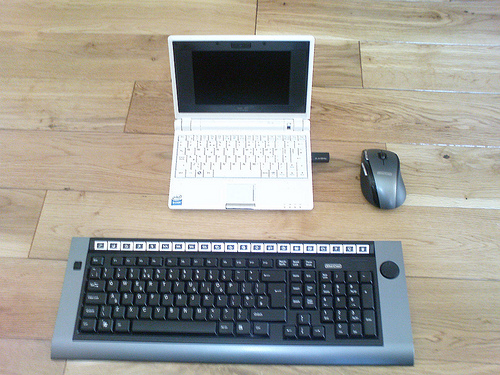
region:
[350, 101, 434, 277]
the mouse is black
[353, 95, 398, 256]
the mouse is gray and black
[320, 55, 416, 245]
the mouse is gray and black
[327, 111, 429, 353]
the mouse is gray and black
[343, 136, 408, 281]
the mouse is gray and black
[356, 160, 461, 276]
the mouse is gray and black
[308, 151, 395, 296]
the mouse is gray and black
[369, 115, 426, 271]
the mouse is gray and black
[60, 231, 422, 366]
A full keyboard in front of the laptop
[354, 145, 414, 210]
A wireless mouse next to the laptop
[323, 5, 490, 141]
Wooden surface beneath the laptop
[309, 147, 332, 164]
Wireless mouse adapter plugged into laptop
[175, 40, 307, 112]
The laptop has a small screen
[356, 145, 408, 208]
The mouse is grey and black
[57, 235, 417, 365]
The keyboard is grey and black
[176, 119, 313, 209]
The laptop is white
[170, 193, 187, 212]
A sticker on the laptop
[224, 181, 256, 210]
A white touchpad on the laptop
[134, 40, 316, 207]
white laptop with black screen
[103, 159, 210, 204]
laptop sitting on wood floor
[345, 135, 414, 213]
black mouse next to laptop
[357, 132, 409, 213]
mouse sitting on floor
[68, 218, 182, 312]
gray and black keyboard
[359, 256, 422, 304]
black circle on keyboard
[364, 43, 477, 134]
floor is wooden and brown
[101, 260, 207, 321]
keys on keyboard are black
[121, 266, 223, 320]
letters on keys are white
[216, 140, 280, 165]
letters on keys are black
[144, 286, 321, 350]
the keyboard is black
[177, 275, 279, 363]
the keyboard is black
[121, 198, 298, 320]
the keyboard is black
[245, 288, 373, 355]
the keyboard is black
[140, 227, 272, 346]
the keyboard is black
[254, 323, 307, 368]
the keyboard is black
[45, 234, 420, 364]
a wireless computer keyboard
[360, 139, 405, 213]
a black and grey computer mouse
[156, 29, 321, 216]
a white laptop computer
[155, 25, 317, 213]
an open notebook computer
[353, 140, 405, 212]
a multi button mouse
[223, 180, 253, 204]
a computer track pad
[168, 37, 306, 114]
a computer monitor screen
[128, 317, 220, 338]
a keyboard space bar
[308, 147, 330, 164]
a USB wireless dongle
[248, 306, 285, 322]
a keyboard shift key